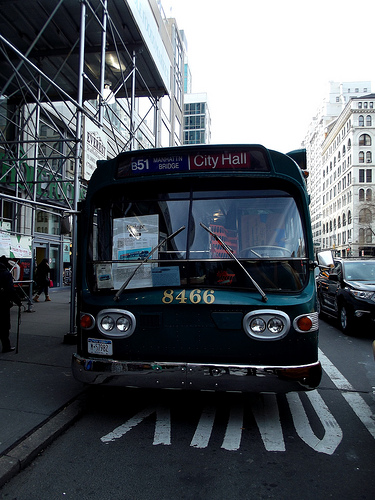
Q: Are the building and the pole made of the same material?
A: No, the building is made of glass and the pole is made of metal.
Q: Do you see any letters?
A: Yes, there are letters.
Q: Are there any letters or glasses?
A: Yes, there are letters.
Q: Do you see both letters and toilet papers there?
A: No, there are letters but no toilet papers.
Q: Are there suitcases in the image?
A: No, there are no suitcases.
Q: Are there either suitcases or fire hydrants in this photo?
A: No, there are no suitcases or fire hydrants.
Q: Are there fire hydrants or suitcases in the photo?
A: No, there are no suitcases or fire hydrants.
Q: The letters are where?
A: The letters are on the road.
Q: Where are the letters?
A: The letters are on the road.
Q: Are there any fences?
A: No, there are no fences.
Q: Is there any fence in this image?
A: No, there are no fences.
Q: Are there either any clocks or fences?
A: No, there are no fences or clocks.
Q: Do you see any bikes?
A: No, there are no bikes.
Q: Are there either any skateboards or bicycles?
A: No, there are no bicycles or skateboards.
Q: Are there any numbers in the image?
A: Yes, there are numbers.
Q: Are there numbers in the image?
A: Yes, there are numbers.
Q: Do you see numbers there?
A: Yes, there are numbers.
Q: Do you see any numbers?
A: Yes, there are numbers.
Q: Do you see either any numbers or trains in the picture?
A: Yes, there are numbers.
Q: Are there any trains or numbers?
A: Yes, there are numbers.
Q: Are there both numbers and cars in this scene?
A: Yes, there are both numbers and a car.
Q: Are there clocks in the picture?
A: No, there are no clocks.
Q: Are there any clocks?
A: No, there are no clocks.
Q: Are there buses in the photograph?
A: Yes, there is a bus.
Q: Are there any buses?
A: Yes, there is a bus.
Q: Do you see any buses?
A: Yes, there is a bus.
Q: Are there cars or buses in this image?
A: Yes, there is a bus.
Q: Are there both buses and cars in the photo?
A: Yes, there are both a bus and a car.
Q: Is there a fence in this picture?
A: No, there are no fences.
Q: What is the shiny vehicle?
A: The vehicle is a bus.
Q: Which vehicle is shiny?
A: The vehicle is a bus.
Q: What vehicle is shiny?
A: The vehicle is a bus.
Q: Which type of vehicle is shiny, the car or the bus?
A: The bus is shiny.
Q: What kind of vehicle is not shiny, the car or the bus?
A: The car is not shiny.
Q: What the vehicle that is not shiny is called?
A: The vehicle is a car.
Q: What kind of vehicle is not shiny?
A: The vehicle is a car.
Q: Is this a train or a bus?
A: This is a bus.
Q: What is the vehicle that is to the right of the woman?
A: The vehicle is a bus.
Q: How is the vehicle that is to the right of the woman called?
A: The vehicle is a bus.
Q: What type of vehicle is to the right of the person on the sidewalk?
A: The vehicle is a bus.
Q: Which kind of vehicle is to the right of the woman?
A: The vehicle is a bus.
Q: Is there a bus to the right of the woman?
A: Yes, there is a bus to the right of the woman.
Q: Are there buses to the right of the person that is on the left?
A: Yes, there is a bus to the right of the woman.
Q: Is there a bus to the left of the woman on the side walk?
A: No, the bus is to the right of the woman.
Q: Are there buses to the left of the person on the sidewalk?
A: No, the bus is to the right of the woman.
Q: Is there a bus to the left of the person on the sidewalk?
A: No, the bus is to the right of the woman.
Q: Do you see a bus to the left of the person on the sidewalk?
A: No, the bus is to the right of the woman.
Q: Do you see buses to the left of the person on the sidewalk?
A: No, the bus is to the right of the woman.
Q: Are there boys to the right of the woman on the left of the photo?
A: No, there is a bus to the right of the woman.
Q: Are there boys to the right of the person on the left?
A: No, there is a bus to the right of the woman.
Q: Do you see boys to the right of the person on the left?
A: No, there is a bus to the right of the woman.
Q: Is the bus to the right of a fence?
A: No, the bus is to the right of a woman.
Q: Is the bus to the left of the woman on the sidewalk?
A: No, the bus is to the right of the woman.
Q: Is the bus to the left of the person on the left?
A: No, the bus is to the right of the woman.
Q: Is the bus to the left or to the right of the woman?
A: The bus is to the right of the woman.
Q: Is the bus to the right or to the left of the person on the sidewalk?
A: The bus is to the right of the woman.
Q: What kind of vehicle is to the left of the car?
A: The vehicle is a bus.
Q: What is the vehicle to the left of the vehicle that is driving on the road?
A: The vehicle is a bus.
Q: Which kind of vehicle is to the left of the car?
A: The vehicle is a bus.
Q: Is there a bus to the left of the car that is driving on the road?
A: Yes, there is a bus to the left of the car.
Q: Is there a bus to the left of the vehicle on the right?
A: Yes, there is a bus to the left of the car.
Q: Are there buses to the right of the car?
A: No, the bus is to the left of the car.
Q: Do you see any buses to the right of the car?
A: No, the bus is to the left of the car.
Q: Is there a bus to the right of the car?
A: No, the bus is to the left of the car.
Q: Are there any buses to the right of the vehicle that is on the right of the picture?
A: No, the bus is to the left of the car.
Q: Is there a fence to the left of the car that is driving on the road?
A: No, there is a bus to the left of the car.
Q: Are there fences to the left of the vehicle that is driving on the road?
A: No, there is a bus to the left of the car.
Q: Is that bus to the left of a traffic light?
A: No, the bus is to the left of a car.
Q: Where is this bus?
A: The bus is on the road.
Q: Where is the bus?
A: The bus is on the road.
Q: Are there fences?
A: No, there are no fences.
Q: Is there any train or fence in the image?
A: No, there are no fences or trains.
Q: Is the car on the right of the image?
A: Yes, the car is on the right of the image.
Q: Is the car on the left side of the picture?
A: No, the car is on the right of the image.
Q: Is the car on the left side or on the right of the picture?
A: The car is on the right of the image.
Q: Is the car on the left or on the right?
A: The car is on the right of the image.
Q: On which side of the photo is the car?
A: The car is on the right of the image.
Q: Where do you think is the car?
A: The car is on the road.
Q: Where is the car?
A: The car is on the road.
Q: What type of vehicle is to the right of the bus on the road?
A: The vehicle is a car.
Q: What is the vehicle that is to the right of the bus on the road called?
A: The vehicle is a car.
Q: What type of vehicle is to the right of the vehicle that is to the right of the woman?
A: The vehicle is a car.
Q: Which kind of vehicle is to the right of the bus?
A: The vehicle is a car.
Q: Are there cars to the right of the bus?
A: Yes, there is a car to the right of the bus.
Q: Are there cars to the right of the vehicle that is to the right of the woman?
A: Yes, there is a car to the right of the bus.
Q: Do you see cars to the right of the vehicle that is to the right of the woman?
A: Yes, there is a car to the right of the bus.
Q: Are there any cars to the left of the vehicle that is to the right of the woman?
A: No, the car is to the right of the bus.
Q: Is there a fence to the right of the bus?
A: No, there is a car to the right of the bus.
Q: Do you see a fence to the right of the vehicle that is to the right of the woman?
A: No, there is a car to the right of the bus.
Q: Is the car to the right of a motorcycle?
A: No, the car is to the right of the bus.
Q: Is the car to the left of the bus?
A: No, the car is to the right of the bus.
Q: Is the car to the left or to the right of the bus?
A: The car is to the right of the bus.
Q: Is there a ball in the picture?
A: No, there are no balls.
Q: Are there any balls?
A: No, there are no balls.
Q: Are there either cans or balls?
A: No, there are no balls or cans.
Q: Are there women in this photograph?
A: Yes, there is a woman.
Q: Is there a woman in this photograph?
A: Yes, there is a woman.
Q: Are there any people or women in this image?
A: Yes, there is a woman.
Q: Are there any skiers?
A: No, there are no skiers.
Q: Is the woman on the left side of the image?
A: Yes, the woman is on the left of the image.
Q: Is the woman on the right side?
A: No, the woman is on the left of the image.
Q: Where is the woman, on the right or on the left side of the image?
A: The woman is on the left of the image.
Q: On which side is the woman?
A: The woman is on the left of the image.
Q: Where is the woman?
A: The woman is on the sidewalk.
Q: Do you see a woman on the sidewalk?
A: Yes, there is a woman on the sidewalk.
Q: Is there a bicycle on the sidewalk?
A: No, there is a woman on the sidewalk.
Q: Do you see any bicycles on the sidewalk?
A: No, there is a woman on the sidewalk.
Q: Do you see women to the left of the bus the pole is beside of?
A: Yes, there is a woman to the left of the bus.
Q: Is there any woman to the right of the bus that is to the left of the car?
A: No, the woman is to the left of the bus.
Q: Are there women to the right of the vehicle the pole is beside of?
A: No, the woman is to the left of the bus.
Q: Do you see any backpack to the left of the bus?
A: No, there is a woman to the left of the bus.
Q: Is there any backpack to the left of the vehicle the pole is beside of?
A: No, there is a woman to the left of the bus.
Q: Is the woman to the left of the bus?
A: Yes, the woman is to the left of the bus.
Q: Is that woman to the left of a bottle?
A: No, the woman is to the left of the bus.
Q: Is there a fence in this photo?
A: No, there are no fences.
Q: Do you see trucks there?
A: No, there are no trucks.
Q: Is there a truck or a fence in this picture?
A: No, there are no trucks or fences.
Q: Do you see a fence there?
A: No, there are no fences.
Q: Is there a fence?
A: No, there are no fences.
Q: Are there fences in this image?
A: No, there are no fences.